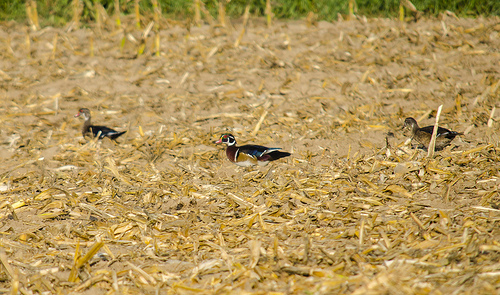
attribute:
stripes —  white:
[224, 132, 239, 149]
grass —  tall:
[0, 0, 487, 42]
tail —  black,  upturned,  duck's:
[109, 117, 129, 144]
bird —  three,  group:
[398, 117, 463, 154]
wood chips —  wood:
[126, 167, 418, 244]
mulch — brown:
[10, 14, 497, 152]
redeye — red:
[223, 135, 227, 141]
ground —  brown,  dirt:
[15, 16, 500, 287]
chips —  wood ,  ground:
[0, 12, 495, 294]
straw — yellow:
[167, 191, 482, 286]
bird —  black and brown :
[396, 115, 466, 157]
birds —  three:
[392, 102, 482, 175]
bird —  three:
[400, 114, 464, 148]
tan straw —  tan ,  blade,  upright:
[376, 99, 482, 180]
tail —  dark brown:
[270, 145, 294, 159]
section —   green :
[254, 149, 261, 156]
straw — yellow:
[124, 163, 257, 252]